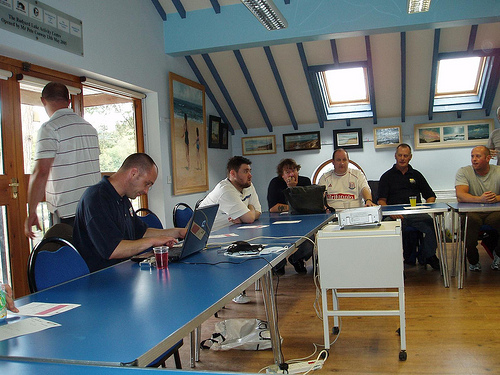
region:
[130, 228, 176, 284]
cup full of red liquid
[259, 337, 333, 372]
a power strip on the floor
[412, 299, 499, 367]
floor is light brown wood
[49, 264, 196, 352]
the table is blue and shiny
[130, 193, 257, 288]
a laptop on the table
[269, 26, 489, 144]
two skylights in the roof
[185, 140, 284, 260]
a man with his arms crossed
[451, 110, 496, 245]
a man with his hands clasped together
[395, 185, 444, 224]
a cup with orange colored juice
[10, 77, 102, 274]
a man looking out the door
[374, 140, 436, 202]
Man in a black shirt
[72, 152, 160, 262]
Man in a blue shirt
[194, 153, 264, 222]
Man with dark hair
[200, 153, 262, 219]
Man in a white shirt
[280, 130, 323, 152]
Picture hanging on the wall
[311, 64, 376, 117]
Window in the ceiling of the room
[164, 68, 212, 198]
Picture of two people on the beach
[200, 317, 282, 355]
Plastic bag on the floor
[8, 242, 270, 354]
Blue table with a drink cup on it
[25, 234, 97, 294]
Blue desk chair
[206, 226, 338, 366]
cords on the table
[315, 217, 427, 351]
white stand on wheels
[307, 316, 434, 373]
the wheels are black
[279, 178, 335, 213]
black bag on the table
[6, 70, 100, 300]
the brown wooden doors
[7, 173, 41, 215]
golden doorknob on the door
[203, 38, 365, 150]
blue and white stripes on the ceiling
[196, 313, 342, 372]
shopping bag under the table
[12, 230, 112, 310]
empty blue and black chair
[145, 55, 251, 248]
picture of children on the beach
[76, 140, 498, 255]
Six men sitting around tables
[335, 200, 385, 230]
A silver projector in the middle of the room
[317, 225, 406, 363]
A metal stand with wheels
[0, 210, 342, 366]
A long blue table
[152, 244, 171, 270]
A plastic cup with a red liquid in it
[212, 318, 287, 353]
A white plastic bag on the floor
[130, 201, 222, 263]
A laptop computer on the blue table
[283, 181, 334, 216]
A black bag on the table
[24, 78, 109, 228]
A man in a white shirt leaving the room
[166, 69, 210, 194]
A wood framed piece of artwork on the wall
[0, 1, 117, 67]
gray and white banner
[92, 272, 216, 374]
blue long desk tables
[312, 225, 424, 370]
moving cart for projecter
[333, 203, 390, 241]
silver projector on cart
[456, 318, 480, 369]
light colored hard wood floors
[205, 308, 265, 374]
white and black plastic bag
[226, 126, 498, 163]
multiple piecs of artwork on the wall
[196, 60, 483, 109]
blie painted ceiling beams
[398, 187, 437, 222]
a glass cup of orange juice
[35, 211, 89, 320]
blue and black chair